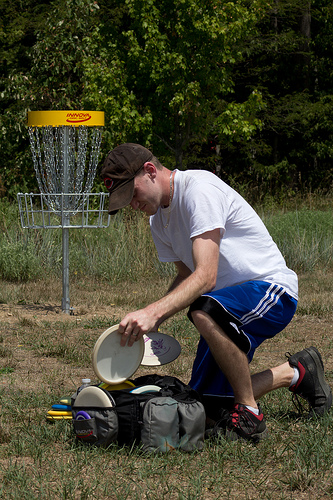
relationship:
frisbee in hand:
[92, 323, 152, 389] [107, 308, 156, 350]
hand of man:
[107, 308, 156, 350] [89, 133, 321, 437]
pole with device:
[59, 176, 82, 309] [22, 109, 105, 218]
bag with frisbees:
[57, 374, 210, 457] [76, 384, 114, 408]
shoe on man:
[202, 397, 273, 447] [89, 133, 321, 437]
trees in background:
[6, 3, 332, 130] [4, 5, 318, 30]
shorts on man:
[188, 273, 299, 406] [89, 133, 321, 437]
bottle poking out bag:
[79, 380, 95, 394] [57, 374, 210, 457]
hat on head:
[95, 144, 156, 215] [94, 147, 176, 224]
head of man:
[94, 147, 176, 224] [89, 133, 321, 437]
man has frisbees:
[89, 133, 321, 437] [76, 384, 114, 408]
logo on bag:
[72, 425, 99, 441] [57, 374, 210, 457]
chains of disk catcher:
[33, 128, 102, 198] [23, 107, 115, 134]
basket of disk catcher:
[16, 189, 114, 238] [23, 107, 115, 134]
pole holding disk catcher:
[59, 176, 82, 309] [23, 107, 115, 134]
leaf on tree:
[86, 64, 94, 72] [35, 7, 149, 117]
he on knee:
[89, 133, 321, 437] [196, 394, 219, 439]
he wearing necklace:
[89, 133, 321, 437] [156, 172, 177, 230]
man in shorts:
[89, 133, 321, 437] [188, 273, 299, 406]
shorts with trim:
[188, 273, 299, 406] [191, 295, 253, 352]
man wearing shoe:
[89, 133, 321, 437] [202, 397, 273, 447]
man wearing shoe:
[89, 133, 321, 437] [285, 347, 332, 424]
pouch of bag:
[143, 399, 185, 458] [57, 374, 210, 457]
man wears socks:
[89, 133, 321, 437] [287, 369, 301, 384]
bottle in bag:
[79, 380, 95, 394] [57, 374, 210, 457]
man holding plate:
[89, 133, 321, 437] [92, 323, 152, 389]